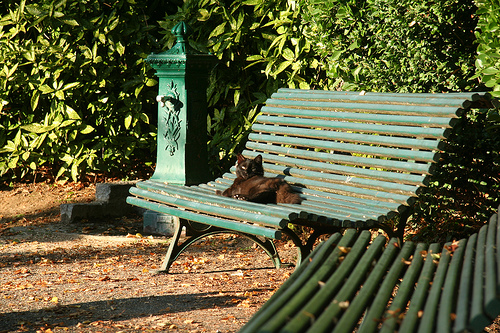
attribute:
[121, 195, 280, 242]
board — green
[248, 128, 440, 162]
board — green